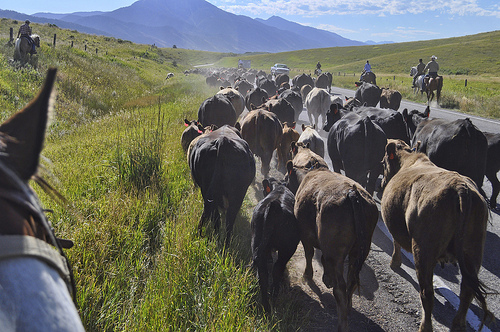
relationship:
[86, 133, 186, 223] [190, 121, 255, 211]
grass next to cow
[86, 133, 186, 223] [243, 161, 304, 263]
grass next to cow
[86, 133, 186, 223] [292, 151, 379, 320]
grass next to brown cow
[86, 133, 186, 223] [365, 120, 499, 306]
grass next to cow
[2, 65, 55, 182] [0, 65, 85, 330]
ear of animal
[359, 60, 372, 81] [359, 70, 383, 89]
man on horse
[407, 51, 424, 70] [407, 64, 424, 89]
person on horse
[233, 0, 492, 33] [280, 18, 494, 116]
clouds above land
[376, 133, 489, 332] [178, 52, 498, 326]
brown cow walking along roadside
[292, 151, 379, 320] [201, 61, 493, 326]
brown cow along roadside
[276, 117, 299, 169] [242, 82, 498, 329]
brown cow along roadside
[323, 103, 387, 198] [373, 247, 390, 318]
black cow along road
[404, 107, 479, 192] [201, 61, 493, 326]
cow along roadside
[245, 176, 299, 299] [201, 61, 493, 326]
black cow along roadside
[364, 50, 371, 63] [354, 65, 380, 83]
man sitting on a horse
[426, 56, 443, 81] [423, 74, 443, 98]
man sitting on a horse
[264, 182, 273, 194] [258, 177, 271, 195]
red tag on cow`s ear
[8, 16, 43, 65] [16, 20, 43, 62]
person riding horse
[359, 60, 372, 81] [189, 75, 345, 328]
man on horse